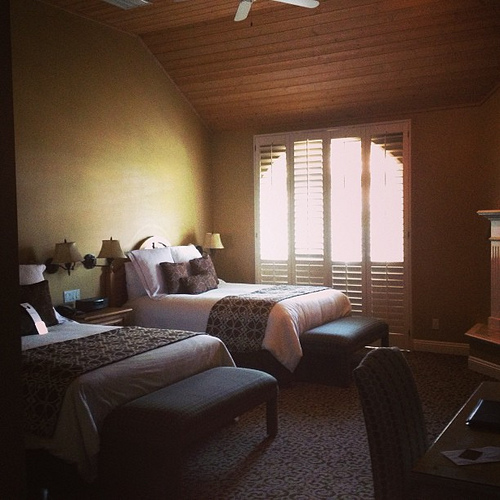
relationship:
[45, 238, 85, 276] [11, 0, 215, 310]
lamp hanging on wall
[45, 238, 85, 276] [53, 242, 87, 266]
lamp has shade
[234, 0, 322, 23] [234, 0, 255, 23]
fan has blade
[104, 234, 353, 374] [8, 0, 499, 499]
bed in room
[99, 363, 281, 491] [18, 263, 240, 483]
bench at end of bed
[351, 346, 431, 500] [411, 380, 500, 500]
chair near desk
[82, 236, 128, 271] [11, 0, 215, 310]
lamp on wall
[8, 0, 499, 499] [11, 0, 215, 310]
room has wall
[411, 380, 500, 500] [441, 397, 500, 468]
desk has objects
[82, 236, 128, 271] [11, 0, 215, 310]
lamp mounted on wall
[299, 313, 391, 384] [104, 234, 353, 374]
bench at end of bed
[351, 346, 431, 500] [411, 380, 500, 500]
chair at desk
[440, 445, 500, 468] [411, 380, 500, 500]
paper on desk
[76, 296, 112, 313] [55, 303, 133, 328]
clock on table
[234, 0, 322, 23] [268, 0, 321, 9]
fan has blade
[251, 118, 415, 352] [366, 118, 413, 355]
shade has panel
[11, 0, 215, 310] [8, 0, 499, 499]
wall in room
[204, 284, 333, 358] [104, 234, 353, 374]
blanket on bed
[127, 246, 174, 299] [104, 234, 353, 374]
pillow on bed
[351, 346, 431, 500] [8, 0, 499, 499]
chair in room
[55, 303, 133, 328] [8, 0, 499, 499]
table in room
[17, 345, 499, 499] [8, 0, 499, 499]
floor in room